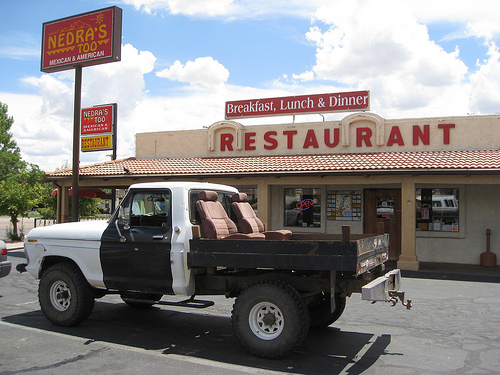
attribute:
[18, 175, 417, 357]
truck — white, black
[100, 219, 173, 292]
door — black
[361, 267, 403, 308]
bumper — metal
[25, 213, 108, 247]
hood — white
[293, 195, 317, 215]
open sign — blue, red, neon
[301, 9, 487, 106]
clouds — white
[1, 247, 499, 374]
parking lot — sunlit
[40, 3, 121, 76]
restaurant sign — red, tall, yellow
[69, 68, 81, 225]
pole — iron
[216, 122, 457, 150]
letters — red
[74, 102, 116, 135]
restaurant sign — red, yellow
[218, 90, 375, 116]
restaurant sign — red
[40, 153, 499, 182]
roof — tile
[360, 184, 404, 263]
door — wooden, brown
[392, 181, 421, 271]
pillar — beige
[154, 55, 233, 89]
cloud — small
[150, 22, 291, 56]
sky — blue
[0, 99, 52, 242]
tree — green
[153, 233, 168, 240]
door handle — metal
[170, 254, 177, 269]
dent — rusty